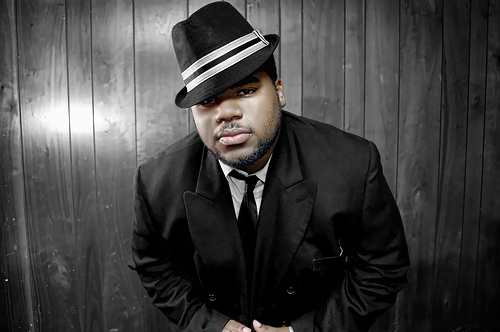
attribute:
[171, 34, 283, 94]
line cap — white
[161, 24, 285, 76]
cap — black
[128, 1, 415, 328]
man — standing, wearing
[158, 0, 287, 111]
hat — black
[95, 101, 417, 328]
coat — black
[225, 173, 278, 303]
tie — man's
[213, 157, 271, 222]
shirt — white